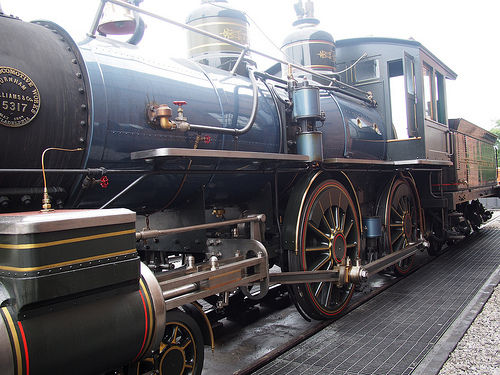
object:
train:
[0, 0, 500, 375]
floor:
[243, 267, 500, 373]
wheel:
[289, 178, 366, 322]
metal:
[144, 9, 190, 30]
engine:
[208, 47, 259, 71]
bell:
[147, 102, 193, 128]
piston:
[2, 251, 150, 335]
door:
[400, 50, 427, 138]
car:
[450, 116, 498, 197]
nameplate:
[0, 67, 42, 129]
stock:
[257, 3, 337, 78]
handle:
[85, 174, 109, 189]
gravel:
[478, 342, 496, 354]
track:
[258, 337, 286, 351]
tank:
[97, 0, 139, 35]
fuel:
[213, 68, 232, 76]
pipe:
[135, 12, 201, 37]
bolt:
[144, 157, 156, 162]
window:
[355, 56, 381, 81]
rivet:
[192, 211, 252, 250]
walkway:
[249, 220, 500, 375]